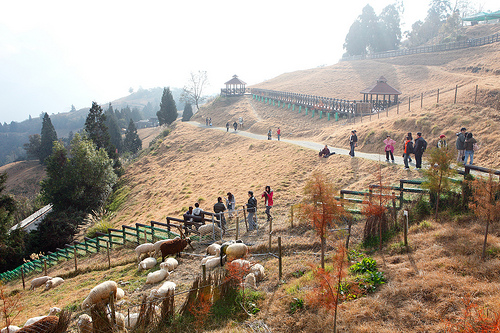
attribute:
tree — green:
[181, 99, 198, 123]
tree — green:
[153, 85, 178, 127]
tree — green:
[121, 117, 142, 155]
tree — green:
[37, 107, 58, 167]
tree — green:
[344, 0, 376, 65]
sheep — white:
[127, 238, 158, 269]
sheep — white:
[132, 250, 159, 270]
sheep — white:
[154, 249, 177, 272]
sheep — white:
[33, 273, 60, 288]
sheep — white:
[137, 265, 167, 286]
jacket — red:
[259, 189, 276, 207]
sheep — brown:
[159, 231, 197, 261]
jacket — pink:
[382, 136, 398, 152]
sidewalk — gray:
[175, 115, 498, 180]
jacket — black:
[242, 193, 258, 218]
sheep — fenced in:
[59, 254, 160, 329]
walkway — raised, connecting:
[249, 82, 354, 122]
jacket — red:
[256, 201, 297, 228]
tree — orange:
[295, 180, 376, 299]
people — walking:
[175, 191, 300, 225]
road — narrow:
[218, 106, 412, 171]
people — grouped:
[161, 190, 324, 242]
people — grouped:
[336, 115, 471, 172]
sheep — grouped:
[81, 242, 261, 330]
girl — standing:
[235, 178, 295, 216]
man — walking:
[335, 126, 379, 166]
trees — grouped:
[21, 112, 152, 229]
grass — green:
[335, 237, 447, 327]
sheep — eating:
[64, 261, 227, 326]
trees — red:
[275, 250, 368, 330]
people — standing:
[361, 145, 459, 179]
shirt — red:
[249, 189, 291, 223]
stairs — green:
[15, 232, 205, 316]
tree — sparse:
[255, 171, 369, 267]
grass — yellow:
[153, 134, 303, 191]